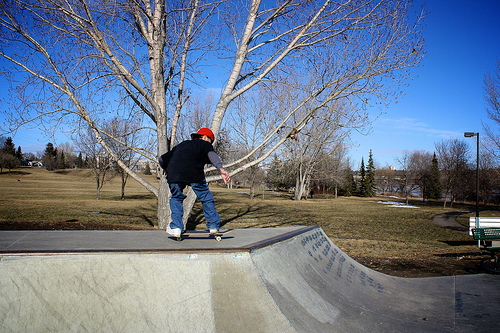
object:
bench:
[467, 216, 500, 249]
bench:
[471, 227, 500, 266]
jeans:
[167, 177, 219, 232]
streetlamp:
[462, 130, 482, 220]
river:
[363, 178, 468, 202]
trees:
[422, 153, 446, 203]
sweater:
[151, 137, 221, 184]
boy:
[154, 124, 234, 236]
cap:
[191, 127, 216, 142]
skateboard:
[164, 228, 234, 241]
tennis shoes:
[165, 226, 183, 238]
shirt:
[155, 138, 215, 182]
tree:
[0, 0, 424, 228]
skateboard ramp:
[248, 229, 500, 333]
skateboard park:
[0, 225, 314, 252]